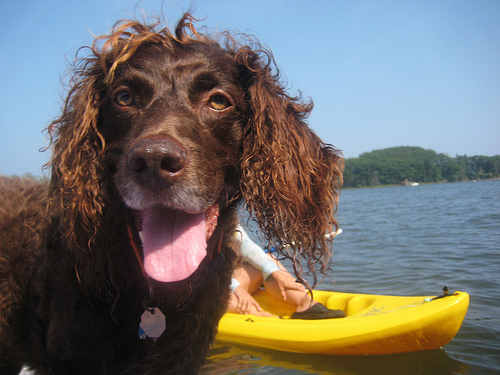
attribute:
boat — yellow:
[212, 285, 473, 356]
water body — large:
[204, 175, 494, 372]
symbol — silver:
[134, 303, 170, 341]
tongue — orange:
[133, 206, 214, 285]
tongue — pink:
[112, 165, 232, 295]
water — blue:
[426, 197, 446, 220]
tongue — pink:
[137, 206, 207, 287]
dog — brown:
[0, 16, 351, 373]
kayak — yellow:
[216, 279, 468, 357]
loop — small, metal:
[140, 293, 160, 317]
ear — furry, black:
[233, 35, 348, 298]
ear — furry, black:
[39, 50, 149, 316]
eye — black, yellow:
[207, 90, 232, 112]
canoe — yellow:
[215, 280, 476, 359]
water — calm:
[328, 177, 495, 283]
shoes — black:
[288, 295, 343, 328]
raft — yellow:
[214, 280, 470, 355]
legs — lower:
[231, 275, 313, 314]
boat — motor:
[219, 278, 468, 345]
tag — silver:
[130, 289, 205, 373]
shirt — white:
[226, 224, 283, 291]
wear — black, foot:
[288, 300, 348, 319]